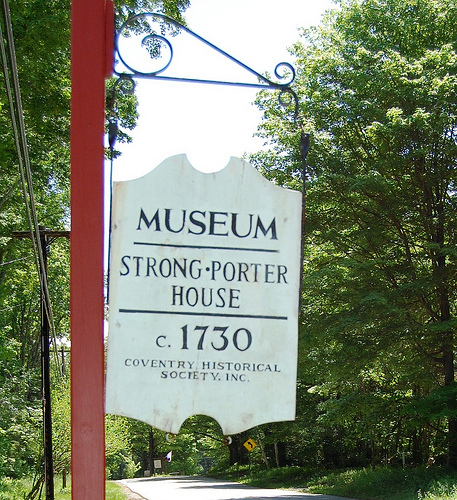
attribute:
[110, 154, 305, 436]
sign — large, white, red, metal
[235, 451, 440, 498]
green grass — patch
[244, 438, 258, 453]
sign — yellow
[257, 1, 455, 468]
trees — tall and green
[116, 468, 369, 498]
road — paved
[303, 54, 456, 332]
tree — large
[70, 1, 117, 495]
pole — red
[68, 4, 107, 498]
post — red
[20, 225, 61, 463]
pole — black , metal 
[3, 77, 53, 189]
pole — wooden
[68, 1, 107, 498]
pole — red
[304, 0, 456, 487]
tree — large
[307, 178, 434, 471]
tree — large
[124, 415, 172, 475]
tree — large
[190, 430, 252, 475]
tree — large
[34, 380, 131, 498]
tree — large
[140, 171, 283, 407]
sign — white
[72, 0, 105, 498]
pole — metal, red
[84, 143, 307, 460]
sign — white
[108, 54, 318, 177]
metal — black